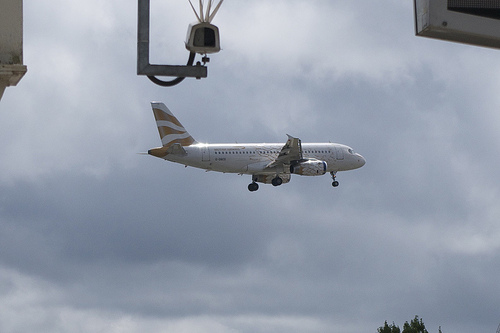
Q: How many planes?
A: 1.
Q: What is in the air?
A: Plane.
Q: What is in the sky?
A: Clouds.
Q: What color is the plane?
A: White.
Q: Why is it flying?
A: To get somewhere.